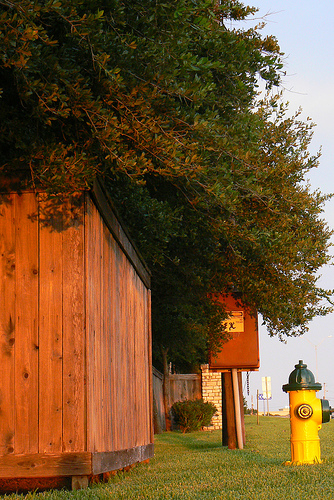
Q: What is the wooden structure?
A: Tall wooden fence.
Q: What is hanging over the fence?
A: Large leafy tree.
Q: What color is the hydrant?
A: Yellow and black.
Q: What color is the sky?
A: Blue.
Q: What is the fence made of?
A: Wood.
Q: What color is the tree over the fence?
A: Green and brown.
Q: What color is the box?
A: Orange.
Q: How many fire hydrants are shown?
A: One.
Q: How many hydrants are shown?
A: 1.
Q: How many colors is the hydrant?
A: 2.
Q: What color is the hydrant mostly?
A: Yellow.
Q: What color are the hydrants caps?
A: Green.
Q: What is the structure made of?
A: Wood.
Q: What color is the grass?
A: Green.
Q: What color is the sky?
A: White.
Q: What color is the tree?
A: Green.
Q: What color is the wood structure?
A: Brown.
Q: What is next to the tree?
A: A fire hydrant.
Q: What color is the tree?
A: Green.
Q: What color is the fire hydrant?
A: Yellow.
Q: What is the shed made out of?
A: Wood.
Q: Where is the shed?
A: Under the tree.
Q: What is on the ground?
A: Grass.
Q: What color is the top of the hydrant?
A: Green.